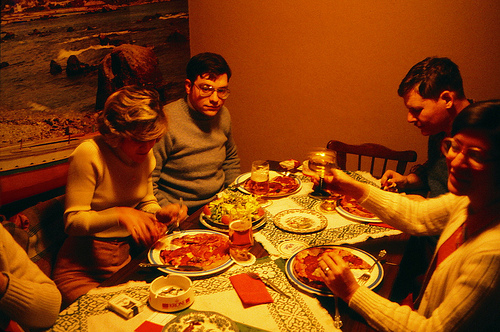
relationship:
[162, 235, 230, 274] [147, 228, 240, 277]
pizza on plate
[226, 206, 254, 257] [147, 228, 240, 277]
glass next to plate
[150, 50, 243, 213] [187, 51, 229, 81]
man has hair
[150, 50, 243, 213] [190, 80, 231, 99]
man has glasses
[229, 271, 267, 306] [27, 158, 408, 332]
napkin on table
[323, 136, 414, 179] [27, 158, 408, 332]
chair at table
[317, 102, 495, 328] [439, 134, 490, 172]
woman has glasses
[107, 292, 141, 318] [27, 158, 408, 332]
cigarettes on table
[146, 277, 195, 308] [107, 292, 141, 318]
ashtray next to cigarettes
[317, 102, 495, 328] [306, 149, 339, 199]
woman holding wine glass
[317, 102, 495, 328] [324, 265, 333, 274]
woman wearing wedding band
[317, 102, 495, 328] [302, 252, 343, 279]
woman holding slice of pizza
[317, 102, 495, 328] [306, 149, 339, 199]
woman holding up wine glass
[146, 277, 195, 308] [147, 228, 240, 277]
ashtray next to plate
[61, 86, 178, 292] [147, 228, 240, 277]
woman has plate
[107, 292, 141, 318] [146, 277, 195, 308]
cigarettes next to ashtray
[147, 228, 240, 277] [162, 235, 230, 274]
plate holds pizza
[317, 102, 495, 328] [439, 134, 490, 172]
woman wearing glasses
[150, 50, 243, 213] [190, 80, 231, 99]
man wearing glasses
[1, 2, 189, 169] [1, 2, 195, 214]
painting on wall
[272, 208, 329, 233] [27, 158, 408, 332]
plate on middle of table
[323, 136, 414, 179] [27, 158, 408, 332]
chair at end of table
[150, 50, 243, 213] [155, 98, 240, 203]
man wearing sweater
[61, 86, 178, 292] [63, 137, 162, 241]
woman wears sweater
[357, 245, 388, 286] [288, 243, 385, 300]
fork on side of plate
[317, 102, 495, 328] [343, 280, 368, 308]
woman has wrist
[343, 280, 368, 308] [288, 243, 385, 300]
wrist on plate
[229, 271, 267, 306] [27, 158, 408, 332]
napkin on middle of table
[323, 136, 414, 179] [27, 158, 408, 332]
chair at head of table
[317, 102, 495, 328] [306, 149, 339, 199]
woman holds up wine glass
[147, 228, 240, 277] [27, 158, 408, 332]
plate on table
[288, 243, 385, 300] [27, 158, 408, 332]
plate on table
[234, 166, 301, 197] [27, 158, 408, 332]
plate on table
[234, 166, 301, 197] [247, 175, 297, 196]
plate has pizza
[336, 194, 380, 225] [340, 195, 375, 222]
plate has pizza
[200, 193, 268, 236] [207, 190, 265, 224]
plate has salad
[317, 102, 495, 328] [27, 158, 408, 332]
woman sits at table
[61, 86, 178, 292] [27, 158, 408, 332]
woman sits at table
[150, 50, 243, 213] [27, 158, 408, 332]
man sits at table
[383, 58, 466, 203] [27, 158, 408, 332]
man sits at table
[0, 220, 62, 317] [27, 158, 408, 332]
person sits at table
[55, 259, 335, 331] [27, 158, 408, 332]
table cloth covers table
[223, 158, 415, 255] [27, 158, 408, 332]
table cloth covers table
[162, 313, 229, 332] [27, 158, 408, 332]
plate on table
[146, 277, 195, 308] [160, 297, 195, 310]
ashtray has lettering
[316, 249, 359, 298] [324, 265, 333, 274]
hand has wedding band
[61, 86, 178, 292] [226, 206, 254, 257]
woman has glass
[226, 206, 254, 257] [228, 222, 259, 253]
glass has beer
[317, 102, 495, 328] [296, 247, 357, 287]
woman has pizza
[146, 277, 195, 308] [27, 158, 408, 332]
ashtray on table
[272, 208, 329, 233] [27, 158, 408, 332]
plate on table